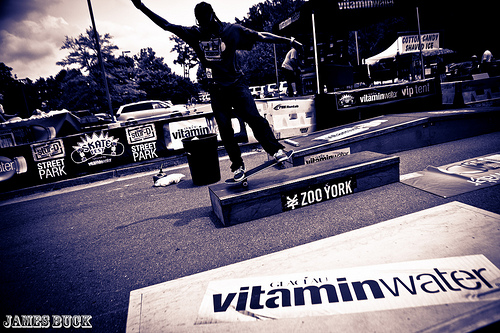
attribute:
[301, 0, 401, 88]
tent —  black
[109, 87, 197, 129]
car — parked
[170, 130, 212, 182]
can — for  garbage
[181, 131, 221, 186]
bin — black, trash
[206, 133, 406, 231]
ramp —  skate's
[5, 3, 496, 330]
area — for skateboarding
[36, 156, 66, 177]
words —  Street Park